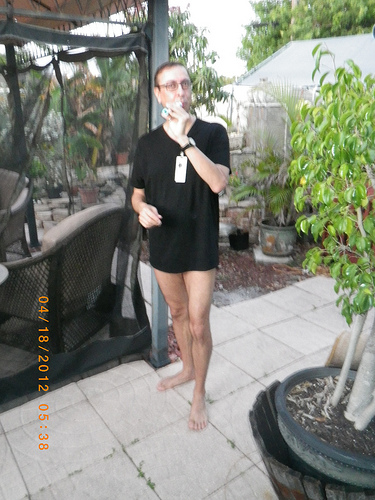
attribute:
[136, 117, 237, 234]
shirt — black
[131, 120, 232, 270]
shirt — black, short sleeved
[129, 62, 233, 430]
man — middle aged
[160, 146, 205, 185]
badge — identification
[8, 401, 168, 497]
tile — white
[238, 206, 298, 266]
pot — green, orange and white flower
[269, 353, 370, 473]
barrel — wooden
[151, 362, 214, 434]
feet — bare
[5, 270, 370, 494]
cement — light colored, square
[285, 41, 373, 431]
tree — small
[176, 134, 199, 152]
watch — black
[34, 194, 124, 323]
chair — dark brown , wicker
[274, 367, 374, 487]
pot — green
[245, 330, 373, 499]
barrel — wooden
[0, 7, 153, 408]
bug netting — black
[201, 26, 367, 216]
tent — white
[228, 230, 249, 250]
pot — black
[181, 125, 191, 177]
band — black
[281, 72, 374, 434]
plant — potted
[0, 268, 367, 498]
tiles — concrete